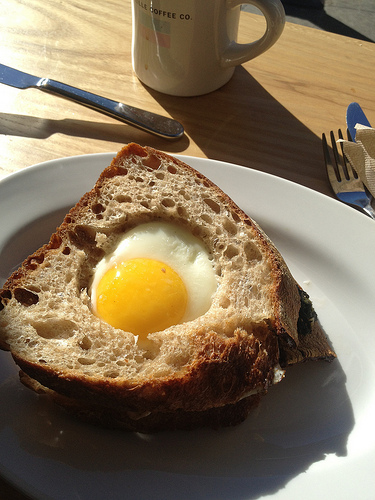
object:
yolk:
[95, 254, 186, 337]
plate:
[0, 150, 374, 498]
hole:
[36, 315, 76, 340]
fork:
[321, 128, 375, 217]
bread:
[0, 141, 302, 416]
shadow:
[0, 113, 190, 154]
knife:
[345, 102, 373, 143]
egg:
[91, 219, 219, 334]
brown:
[209, 365, 226, 394]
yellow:
[121, 285, 153, 331]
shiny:
[34, 75, 50, 87]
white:
[170, 27, 186, 57]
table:
[0, 0, 374, 497]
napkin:
[333, 121, 375, 201]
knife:
[0, 62, 185, 140]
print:
[136, 24, 171, 50]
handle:
[224, 1, 285, 67]